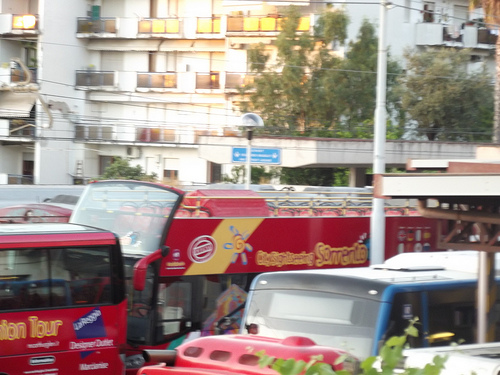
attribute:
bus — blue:
[241, 257, 498, 340]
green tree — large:
[258, 16, 365, 132]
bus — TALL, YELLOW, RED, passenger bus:
[71, 177, 494, 372]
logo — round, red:
[187, 233, 214, 263]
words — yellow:
[1, 311, 63, 341]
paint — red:
[166, 217, 368, 263]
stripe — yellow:
[183, 216, 265, 276]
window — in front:
[397, 290, 424, 350]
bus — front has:
[239, 249, 498, 361]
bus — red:
[80, 181, 496, 351]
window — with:
[428, 286, 478, 346]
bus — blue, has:
[245, 250, 499, 370]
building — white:
[7, 5, 472, 186]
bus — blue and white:
[71, 178, 438, 359]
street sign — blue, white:
[227, 142, 286, 168]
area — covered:
[367, 153, 497, 370]